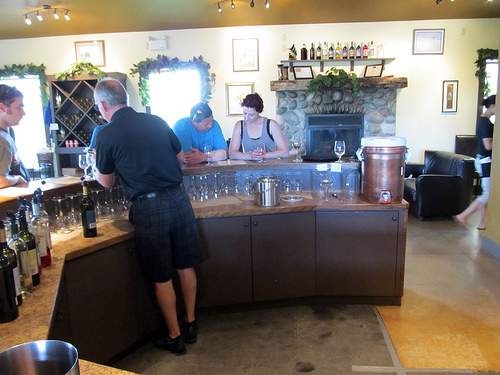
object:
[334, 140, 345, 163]
wine glass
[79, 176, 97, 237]
alcohol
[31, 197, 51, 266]
alcohol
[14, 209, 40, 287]
alcohol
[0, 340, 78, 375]
bowl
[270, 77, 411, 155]
fireplace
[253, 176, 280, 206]
bucket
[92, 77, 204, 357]
bartender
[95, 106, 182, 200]
shirt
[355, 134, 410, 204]
dispenser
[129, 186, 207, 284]
pants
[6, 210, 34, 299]
bottles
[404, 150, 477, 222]
chair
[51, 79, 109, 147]
cubby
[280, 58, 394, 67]
shelf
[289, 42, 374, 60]
bottles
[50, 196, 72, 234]
glass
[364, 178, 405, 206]
beverages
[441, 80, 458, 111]
picture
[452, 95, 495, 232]
woman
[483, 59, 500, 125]
window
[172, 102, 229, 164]
man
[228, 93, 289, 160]
woman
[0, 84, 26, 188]
man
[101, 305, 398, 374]
mat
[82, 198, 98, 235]
wine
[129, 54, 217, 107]
wreath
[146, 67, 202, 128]
window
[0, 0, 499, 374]
room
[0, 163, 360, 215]
bar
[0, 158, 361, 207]
counter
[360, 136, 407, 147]
lid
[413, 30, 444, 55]
diploma